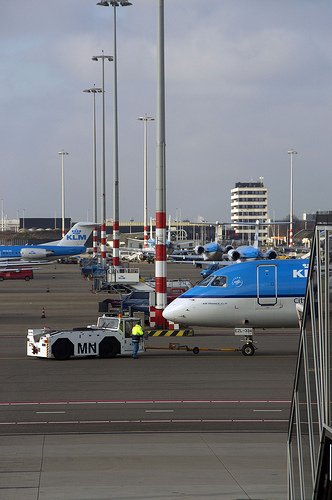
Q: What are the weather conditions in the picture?
A: It is cloudy.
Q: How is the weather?
A: It is cloudy.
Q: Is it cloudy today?
A: Yes, it is cloudy.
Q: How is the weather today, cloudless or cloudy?
A: It is cloudy.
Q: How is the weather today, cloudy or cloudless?
A: It is cloudy.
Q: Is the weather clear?
A: No, it is cloudy.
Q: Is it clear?
A: No, it is cloudy.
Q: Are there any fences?
A: No, there are no fences.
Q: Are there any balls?
A: No, there are no balls.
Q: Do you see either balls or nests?
A: No, there are no balls or nests.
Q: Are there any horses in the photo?
A: No, there are no horses.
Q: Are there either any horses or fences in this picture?
A: No, there are no horses or fences.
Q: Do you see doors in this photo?
A: Yes, there is a door.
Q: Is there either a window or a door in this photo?
A: Yes, there is a door.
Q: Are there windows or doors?
A: Yes, there is a door.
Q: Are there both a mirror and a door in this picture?
A: No, there is a door but no mirrors.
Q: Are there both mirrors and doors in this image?
A: No, there is a door but no mirrors.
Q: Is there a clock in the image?
A: No, there are no clocks.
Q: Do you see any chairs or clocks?
A: No, there are no clocks or chairs.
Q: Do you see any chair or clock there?
A: No, there are no clocks or chairs.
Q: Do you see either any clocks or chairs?
A: No, there are no clocks or chairs.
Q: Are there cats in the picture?
A: No, there are no cats.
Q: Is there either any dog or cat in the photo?
A: No, there are no cats or dogs.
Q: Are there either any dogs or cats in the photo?
A: No, there are no cats or dogs.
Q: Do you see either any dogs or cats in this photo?
A: No, there are no cats or dogs.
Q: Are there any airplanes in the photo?
A: Yes, there is an airplane.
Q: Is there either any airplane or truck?
A: Yes, there is an airplane.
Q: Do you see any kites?
A: No, there are no kites.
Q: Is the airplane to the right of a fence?
A: No, the airplane is to the right of the vehicle.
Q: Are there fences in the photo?
A: No, there are no fences.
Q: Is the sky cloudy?
A: Yes, the sky is cloudy.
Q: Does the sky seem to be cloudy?
A: Yes, the sky is cloudy.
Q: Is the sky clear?
A: No, the sky is cloudy.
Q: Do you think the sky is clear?
A: No, the sky is cloudy.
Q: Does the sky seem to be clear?
A: No, the sky is cloudy.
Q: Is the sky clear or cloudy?
A: The sky is cloudy.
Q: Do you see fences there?
A: No, there are no fences.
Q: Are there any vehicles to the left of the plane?
A: Yes, there is a vehicle to the left of the plane.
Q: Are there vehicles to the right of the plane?
A: No, the vehicle is to the left of the plane.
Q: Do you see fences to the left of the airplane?
A: No, there is a vehicle to the left of the airplane.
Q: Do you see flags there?
A: No, there are no flags.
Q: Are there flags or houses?
A: No, there are no flags or houses.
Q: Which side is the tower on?
A: The tower is on the right of the image.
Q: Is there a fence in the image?
A: No, there are no fences.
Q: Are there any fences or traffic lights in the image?
A: No, there are no fences or traffic lights.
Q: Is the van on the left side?
A: Yes, the van is on the left of the image.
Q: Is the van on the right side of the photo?
A: No, the van is on the left of the image.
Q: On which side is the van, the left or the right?
A: The van is on the left of the image.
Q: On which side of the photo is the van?
A: The van is on the left of the image.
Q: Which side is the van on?
A: The van is on the left of the image.